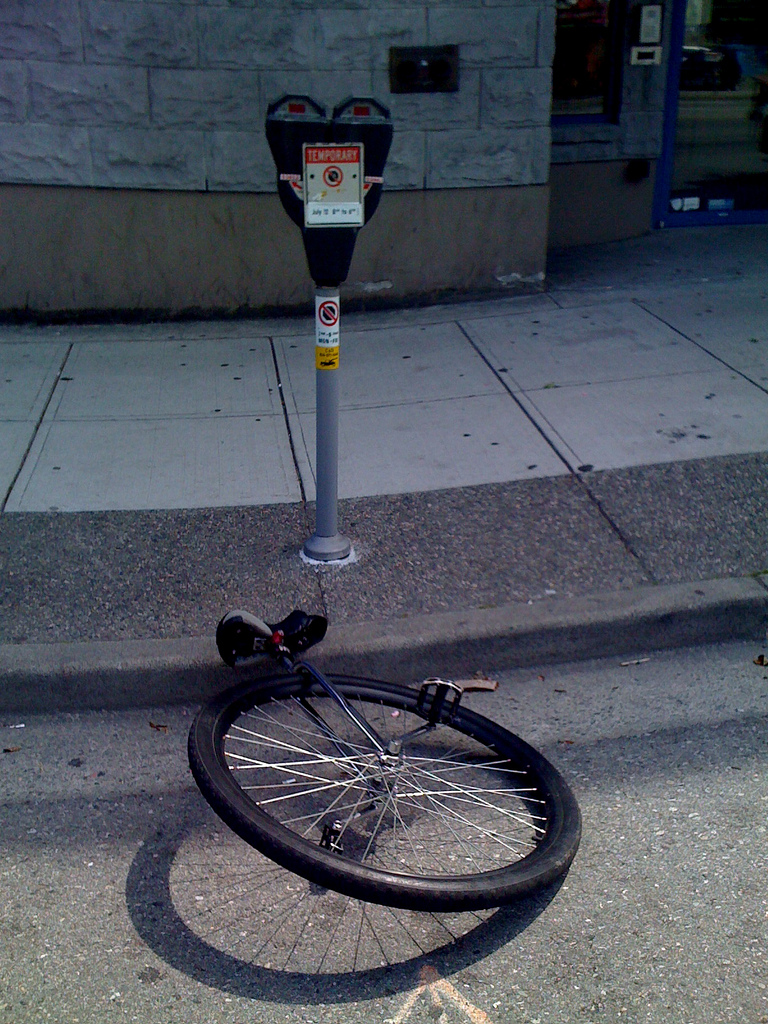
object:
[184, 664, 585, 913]
wheel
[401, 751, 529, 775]
spokes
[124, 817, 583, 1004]
shadow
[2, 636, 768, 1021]
street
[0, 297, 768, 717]
sidewalk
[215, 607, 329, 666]
seat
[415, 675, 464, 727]
pedals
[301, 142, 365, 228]
sign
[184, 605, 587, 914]
bike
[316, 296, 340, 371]
sticker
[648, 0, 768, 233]
door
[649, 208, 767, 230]
frame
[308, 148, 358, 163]
wording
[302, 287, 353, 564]
pole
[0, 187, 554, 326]
brick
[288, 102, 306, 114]
numbers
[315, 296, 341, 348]
sign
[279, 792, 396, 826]
spokes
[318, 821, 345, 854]
pedal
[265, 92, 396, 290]
meter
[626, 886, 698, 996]
top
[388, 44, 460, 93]
plate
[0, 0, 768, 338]
building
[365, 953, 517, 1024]
arrow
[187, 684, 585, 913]
cycle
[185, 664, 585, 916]
tire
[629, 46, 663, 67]
box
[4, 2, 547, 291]
wall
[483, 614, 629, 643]
edge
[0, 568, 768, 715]
curb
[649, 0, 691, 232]
door frame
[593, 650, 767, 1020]
ground